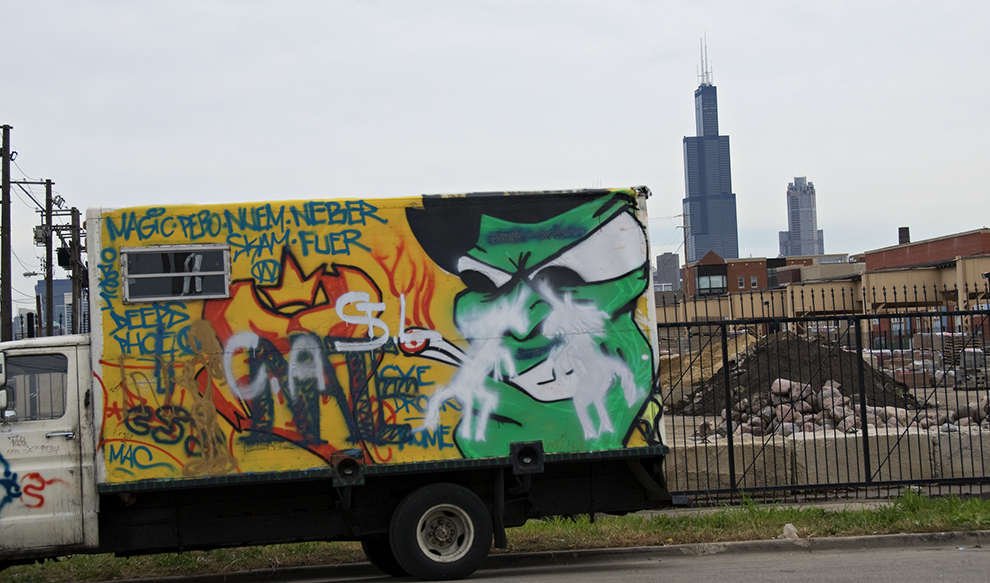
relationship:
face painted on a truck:
[401, 192, 653, 462] [16, 181, 678, 557]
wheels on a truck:
[352, 484, 499, 557] [16, 181, 678, 557]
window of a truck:
[9, 347, 73, 444] [16, 181, 678, 557]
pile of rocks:
[723, 369, 921, 446] [688, 378, 990, 442]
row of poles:
[10, 131, 85, 321] [10, 117, 83, 320]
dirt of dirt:
[664, 330, 926, 417] [687, 327, 913, 417]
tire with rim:
[387, 481, 494, 582] [414, 500, 477, 561]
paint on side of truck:
[219, 277, 649, 446] [0, 184, 681, 582]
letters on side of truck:
[99, 199, 396, 299] [16, 181, 678, 557]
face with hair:
[404, 186, 652, 461] [396, 189, 599, 264]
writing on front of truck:
[9, 450, 52, 523] [16, 181, 678, 557]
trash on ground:
[772, 502, 806, 545] [214, 493, 953, 556]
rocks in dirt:
[718, 374, 901, 446] [685, 333, 906, 408]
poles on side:
[3, 151, 76, 322] [1, 14, 119, 550]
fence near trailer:
[662, 286, 960, 505] [77, 172, 674, 514]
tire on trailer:
[381, 471, 496, 571] [88, 180, 676, 545]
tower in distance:
[676, 34, 746, 307] [667, 59, 949, 248]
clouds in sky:
[230, 30, 408, 174] [7, 7, 961, 338]